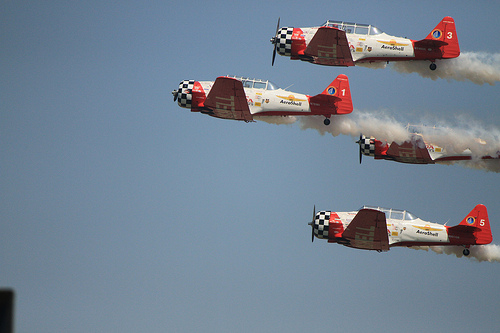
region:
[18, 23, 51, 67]
white clouds in blue sky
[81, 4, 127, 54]
white clouds in blue sky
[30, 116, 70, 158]
white clouds in blue sky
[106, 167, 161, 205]
white clouds in blue sky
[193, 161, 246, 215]
white clouds in blue sky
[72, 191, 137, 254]
white clouds in blue sky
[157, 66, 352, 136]
red and white airplane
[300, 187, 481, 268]
red and white airplane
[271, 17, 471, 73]
red and white airplane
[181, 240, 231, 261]
white clouds in blue sky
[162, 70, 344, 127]
RED AND WHITE PROPELLER PLANE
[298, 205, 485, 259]
RED AND WHITE PROPELLER PLANE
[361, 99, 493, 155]
RED AND WHITE PROPELLER PLANE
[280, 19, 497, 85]
RED AND WHITE PROPELLER PLANE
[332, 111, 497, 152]
WHITE SMOKE BEHIND PLANE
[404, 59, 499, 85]
WHITE SMOKE BEHIND PLANE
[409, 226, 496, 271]
WHITE SMOKE BEHIND PLANE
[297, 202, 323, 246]
CHECKERED FRONT OF PLANE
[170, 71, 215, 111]
CHECKERED FRONT OF PLANE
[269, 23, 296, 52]
CHECKERED FRONT OF PLANE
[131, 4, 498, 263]
plane flying with smoke coming out -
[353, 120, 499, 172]
a plane covered with smoke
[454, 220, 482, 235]
a horizontal stabilizer of the plane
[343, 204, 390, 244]
a wing of the plane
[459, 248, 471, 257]
a landing gear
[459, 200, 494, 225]
a vertical stabilizer of the plane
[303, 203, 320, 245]
a propeller of the plane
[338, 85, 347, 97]
a number one printed on the plane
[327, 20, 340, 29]
a pilot in the plane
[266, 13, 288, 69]
a propeller of the plane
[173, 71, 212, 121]
the planes tip is checkered.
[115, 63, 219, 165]
the plane tip is checkered black and white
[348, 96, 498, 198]
smoke is coming out of the back of the plane.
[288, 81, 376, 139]
each plane is numbered.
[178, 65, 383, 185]
the wing of the plane is red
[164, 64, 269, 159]
the wing of the plane has white writing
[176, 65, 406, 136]
the plane is in the sky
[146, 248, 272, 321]
the sky is a dark shade of blue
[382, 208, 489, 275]
the yellow emblem is on the plane.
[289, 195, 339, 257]
the propellers are black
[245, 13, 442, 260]
four planes are in the air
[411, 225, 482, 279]
smoke is coming from the tail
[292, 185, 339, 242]
the propeller is in front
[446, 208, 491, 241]
the tail is red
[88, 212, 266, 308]
the sky is clear and blue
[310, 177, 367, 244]
the front is black and white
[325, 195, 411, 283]
the wings are red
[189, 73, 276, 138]
white writing is on the wings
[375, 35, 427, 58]
graphics ar eon the plane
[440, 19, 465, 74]
a number is on the tail